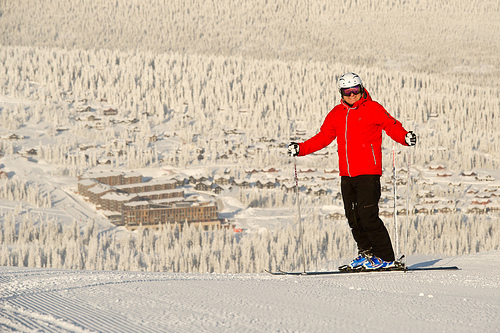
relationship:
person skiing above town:
[292, 72, 414, 274] [71, 163, 499, 226]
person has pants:
[292, 72, 414, 274] [337, 173, 402, 261]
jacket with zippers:
[296, 88, 408, 176] [342, 101, 352, 176]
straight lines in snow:
[9, 287, 134, 331] [4, 256, 494, 331]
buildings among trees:
[78, 171, 222, 231] [0, 47, 498, 272]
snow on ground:
[4, 256, 494, 331] [3, 254, 497, 331]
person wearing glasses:
[287, 72, 417, 270] [338, 89, 361, 97]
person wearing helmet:
[287, 72, 417, 270] [336, 72, 363, 99]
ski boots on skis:
[341, 247, 403, 267] [266, 265, 468, 277]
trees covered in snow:
[6, 9, 316, 126] [20, 36, 251, 165]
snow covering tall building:
[3, 1, 497, 329] [123, 195, 220, 227]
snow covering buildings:
[3, 1, 497, 329] [78, 171, 222, 231]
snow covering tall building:
[3, 1, 497, 329] [89, 180, 174, 202]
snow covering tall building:
[3, 1, 497, 329] [75, 167, 141, 191]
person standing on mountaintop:
[287, 72, 417, 270] [11, 253, 482, 328]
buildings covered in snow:
[78, 170, 235, 233] [4, 256, 494, 331]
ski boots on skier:
[345, 250, 402, 276] [259, 64, 461, 289]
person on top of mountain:
[292, 72, 414, 274] [4, 240, 499, 331]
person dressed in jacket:
[292, 72, 414, 274] [296, 88, 408, 176]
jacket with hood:
[296, 88, 408, 176] [356, 78, 374, 101]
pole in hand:
[294, 156, 306, 274] [283, 138, 305, 166]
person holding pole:
[292, 72, 414, 274] [294, 156, 306, 274]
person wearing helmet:
[292, 72, 414, 274] [337, 71, 363, 96]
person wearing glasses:
[292, 72, 414, 274] [338, 89, 361, 97]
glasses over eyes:
[338, 89, 361, 97] [339, 84, 359, 97]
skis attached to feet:
[279, 266, 459, 275] [340, 249, 400, 269]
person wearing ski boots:
[287, 72, 417, 270] [338, 252, 375, 269]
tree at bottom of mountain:
[198, 252, 210, 268] [1, 251, 498, 328]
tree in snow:
[236, 169, 263, 207] [3, 1, 497, 329]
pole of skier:
[294, 156, 306, 274] [293, 88, 425, 277]